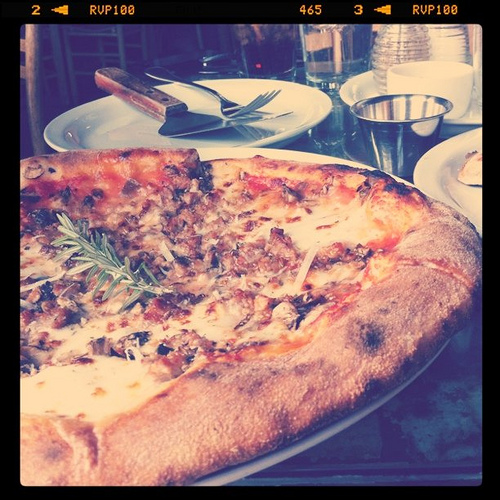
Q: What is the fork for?
A: Eating.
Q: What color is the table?
A: Green.